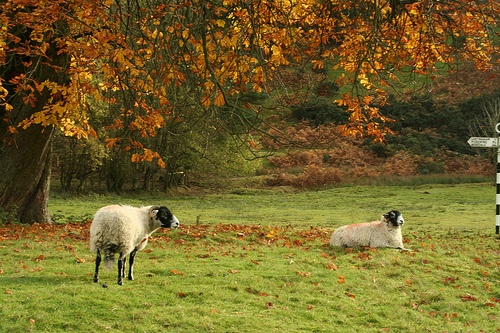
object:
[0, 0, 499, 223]
tree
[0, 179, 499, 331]
ground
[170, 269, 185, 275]
fallen leaves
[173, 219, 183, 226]
nose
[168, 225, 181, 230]
mouth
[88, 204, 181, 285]
ram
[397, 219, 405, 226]
nose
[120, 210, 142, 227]
wool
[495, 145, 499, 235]
signpost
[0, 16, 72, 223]
trunk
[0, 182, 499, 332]
grass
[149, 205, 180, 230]
head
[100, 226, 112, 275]
tail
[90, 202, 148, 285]
body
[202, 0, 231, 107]
branches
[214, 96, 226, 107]
autumn leaves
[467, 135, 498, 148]
arrow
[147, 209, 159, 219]
horns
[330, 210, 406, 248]
sheep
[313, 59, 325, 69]
leaves